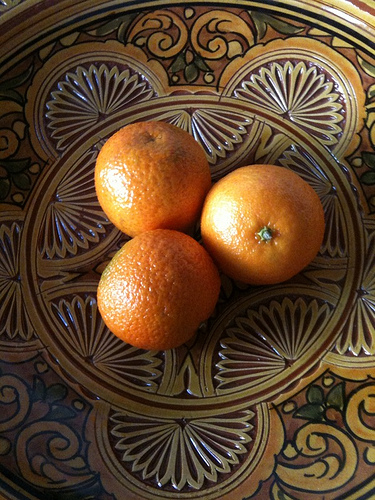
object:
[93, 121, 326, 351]
group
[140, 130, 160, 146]
spot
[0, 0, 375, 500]
design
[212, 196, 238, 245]
reflection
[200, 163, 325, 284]
skin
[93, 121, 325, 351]
orange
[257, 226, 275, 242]
stem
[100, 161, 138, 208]
reflection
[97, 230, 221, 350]
rind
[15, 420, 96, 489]
pattern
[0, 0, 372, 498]
plate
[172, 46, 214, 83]
pattern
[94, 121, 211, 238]
fruit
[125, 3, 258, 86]
paint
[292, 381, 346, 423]
leaf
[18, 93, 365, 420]
circle